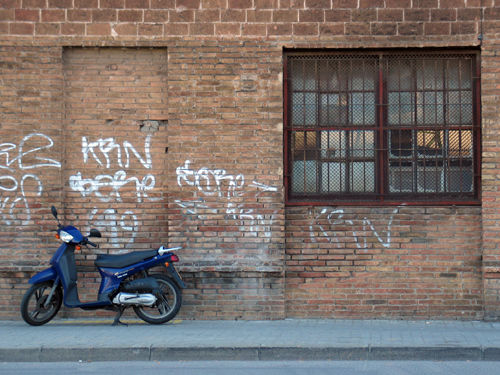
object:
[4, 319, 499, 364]
curb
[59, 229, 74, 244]
light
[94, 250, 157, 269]
rug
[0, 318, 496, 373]
pavement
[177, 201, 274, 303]
white paint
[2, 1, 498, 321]
building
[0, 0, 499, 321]
brown wall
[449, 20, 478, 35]
brick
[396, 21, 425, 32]
brick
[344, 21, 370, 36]
brick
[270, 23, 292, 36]
brick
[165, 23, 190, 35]
brick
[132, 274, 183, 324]
wheel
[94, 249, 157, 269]
seat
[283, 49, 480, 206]
bars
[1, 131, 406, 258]
graffitti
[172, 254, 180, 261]
lights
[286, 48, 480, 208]
mesh wire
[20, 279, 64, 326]
wheel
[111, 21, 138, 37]
bricks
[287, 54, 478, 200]
window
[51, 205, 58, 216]
mirror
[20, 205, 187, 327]
bike